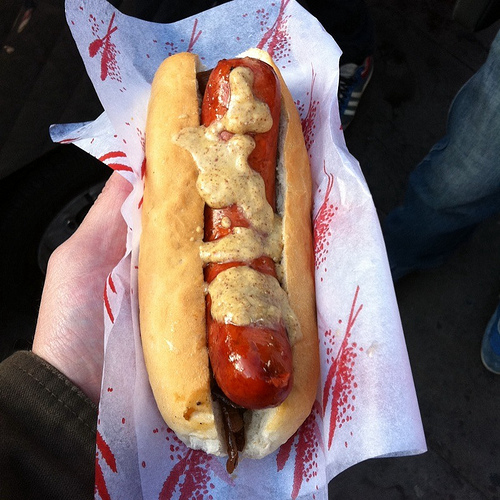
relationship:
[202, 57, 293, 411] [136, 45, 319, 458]
hotdog in bun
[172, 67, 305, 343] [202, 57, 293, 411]
mustard on hotdog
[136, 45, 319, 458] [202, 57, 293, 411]
bun for hotdog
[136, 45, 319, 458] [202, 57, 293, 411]
bun fort hotdog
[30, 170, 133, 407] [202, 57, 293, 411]
hand holding hotdog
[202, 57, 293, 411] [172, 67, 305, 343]
hotdog with mustard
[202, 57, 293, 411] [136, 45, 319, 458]
hotdog on bun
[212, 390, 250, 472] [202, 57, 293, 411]
onion under hotdog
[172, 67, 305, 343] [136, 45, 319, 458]
mustard on bun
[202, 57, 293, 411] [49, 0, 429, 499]
hotdog on paper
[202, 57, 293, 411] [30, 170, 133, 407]
hotdog in hand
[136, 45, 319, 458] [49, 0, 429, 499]
bun in paper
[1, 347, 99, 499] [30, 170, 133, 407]
sleeve near hand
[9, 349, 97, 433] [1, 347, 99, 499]
seam of sleeve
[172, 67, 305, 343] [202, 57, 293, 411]
mustard over hotdog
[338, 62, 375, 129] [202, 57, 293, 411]
shoe behind hotdog